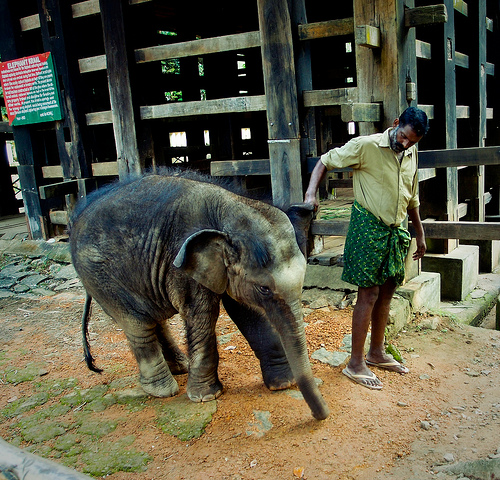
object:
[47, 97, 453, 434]
man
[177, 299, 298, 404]
legs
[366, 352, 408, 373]
flip flop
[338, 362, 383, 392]
flip flop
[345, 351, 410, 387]
feet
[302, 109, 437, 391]
man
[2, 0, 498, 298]
structure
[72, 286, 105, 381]
tail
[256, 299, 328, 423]
trunk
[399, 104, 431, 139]
hair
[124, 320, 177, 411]
back leg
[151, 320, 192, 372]
back leg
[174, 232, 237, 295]
ear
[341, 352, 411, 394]
flip flops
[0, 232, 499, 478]
ground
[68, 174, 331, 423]
elephant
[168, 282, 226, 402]
leg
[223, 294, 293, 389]
leg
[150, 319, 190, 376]
leg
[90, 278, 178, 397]
leg